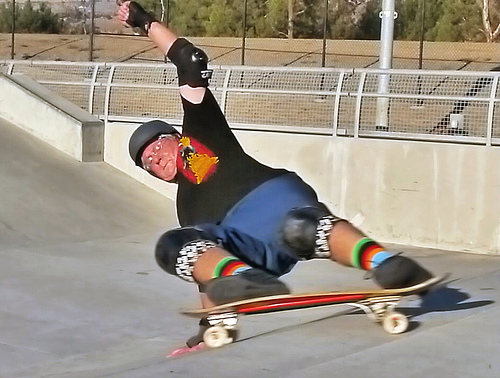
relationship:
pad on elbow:
[167, 38, 213, 89] [187, 50, 211, 64]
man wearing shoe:
[117, 0, 433, 359] [205, 267, 290, 306]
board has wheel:
[179, 270, 456, 350] [383, 312, 410, 335]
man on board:
[117, 0, 433, 359] [179, 270, 456, 350]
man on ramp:
[117, 0, 433, 359] [0, 116, 183, 251]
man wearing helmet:
[117, 0, 433, 359] [128, 119, 182, 165]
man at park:
[117, 0, 433, 359] [1, 58, 499, 377]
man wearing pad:
[117, 0, 433, 359] [167, 38, 213, 89]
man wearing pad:
[117, 0, 433, 359] [278, 203, 349, 260]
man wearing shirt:
[117, 0, 433, 359] [176, 85, 296, 229]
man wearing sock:
[117, 0, 433, 359] [350, 236, 393, 272]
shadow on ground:
[428, 69, 499, 133] [0, 32, 500, 377]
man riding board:
[117, 0, 433, 359] [179, 270, 456, 350]